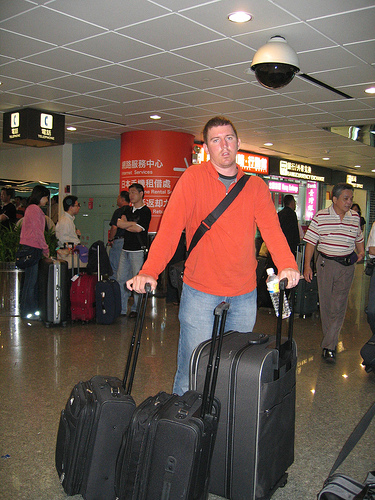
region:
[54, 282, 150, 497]
a black piece of luggage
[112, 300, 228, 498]
a black piece of luggage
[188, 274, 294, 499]
a black piece of luggage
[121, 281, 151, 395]
an extended luggage handle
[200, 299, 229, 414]
an extended luggage handle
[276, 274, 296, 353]
an extended luggage handle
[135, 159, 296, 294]
a long sleeve orange sweatshirt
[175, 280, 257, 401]
a pair of faded blue jeans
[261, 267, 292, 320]
a clear plastic water bottle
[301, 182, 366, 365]
a man walking in airport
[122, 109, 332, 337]
man wearing orange sweater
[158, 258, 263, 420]
man wearing blue jeans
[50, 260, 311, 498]
three black rolling suit cases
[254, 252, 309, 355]
man holding water bottle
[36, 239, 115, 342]
red rolling suitcase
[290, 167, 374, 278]
man wearing striped shirt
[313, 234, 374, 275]
man wearing a pouch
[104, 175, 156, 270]
man wearing black and white shirt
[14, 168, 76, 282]
lady wearing pink sweater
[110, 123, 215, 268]
orange pillar with asian writing on it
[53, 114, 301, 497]
Man with three black suitcases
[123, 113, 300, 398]
Man wearing an orange long sleeve shirt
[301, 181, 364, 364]
Man wearing a striped shirt and brown pants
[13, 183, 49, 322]
Woman wearing pink top and jeans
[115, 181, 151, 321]
Man standing with his arms folded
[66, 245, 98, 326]
Red suitcase on wheels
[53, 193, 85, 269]
Man wearing khaki pants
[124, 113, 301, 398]
Man holding a plastic water bottle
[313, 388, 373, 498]
Gray and black luggage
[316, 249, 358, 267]
Black fanny pack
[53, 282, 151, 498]
a black suitcase with a handle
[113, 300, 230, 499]
a black suitcase with a handle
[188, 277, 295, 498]
a black suitcase with a handle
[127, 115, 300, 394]
a man in a red jacket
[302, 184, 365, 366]
a man in a striped shirt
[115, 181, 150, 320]
a man in a black shirt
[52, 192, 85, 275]
a man in a white shirt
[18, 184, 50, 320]
a woman in a pink shirt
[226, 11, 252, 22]
a recessed lighting fixture in ceiling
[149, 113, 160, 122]
a recessed lighting fixture in ceiling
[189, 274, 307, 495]
a large black suitcase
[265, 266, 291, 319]
a clear water bottle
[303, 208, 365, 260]
a man's striped shirt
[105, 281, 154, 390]
a long black suitcase handle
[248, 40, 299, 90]
a black and white security camera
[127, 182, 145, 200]
short cut black hair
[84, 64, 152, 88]
a white ceiling tile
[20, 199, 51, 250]
a woman's pink shirt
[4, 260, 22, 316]
a gray trashcan